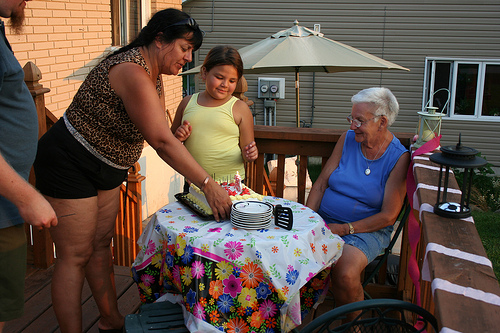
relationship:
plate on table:
[235, 196, 273, 228] [160, 194, 327, 270]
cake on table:
[188, 180, 263, 215] [160, 194, 327, 270]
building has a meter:
[183, 4, 499, 165] [256, 78, 285, 109]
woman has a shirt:
[34, 9, 234, 332] [68, 49, 160, 170]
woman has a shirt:
[305, 86, 412, 333] [322, 130, 411, 235]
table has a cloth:
[160, 194, 327, 270] [132, 193, 345, 331]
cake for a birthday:
[188, 180, 263, 215] [213, 172, 244, 193]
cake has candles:
[188, 180, 263, 215] [214, 175, 243, 192]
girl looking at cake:
[172, 45, 258, 195] [188, 180, 263, 215]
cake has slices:
[188, 180, 263, 215] [246, 192, 263, 211]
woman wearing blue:
[305, 86, 412, 333] [316, 128, 410, 237]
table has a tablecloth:
[160, 194, 327, 270] [128, 194, 345, 332]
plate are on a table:
[235, 196, 273, 228] [160, 194, 327, 270]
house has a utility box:
[2, 2, 184, 129] [257, 77, 284, 128]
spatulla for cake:
[266, 203, 295, 231] [188, 180, 263, 215]